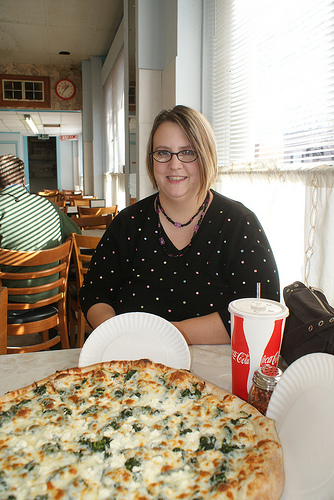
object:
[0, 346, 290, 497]
pizza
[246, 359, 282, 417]
jar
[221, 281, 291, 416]
cup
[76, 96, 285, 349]
woman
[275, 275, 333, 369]
purse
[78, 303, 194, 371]
plate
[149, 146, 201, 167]
glasses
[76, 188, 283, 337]
shirt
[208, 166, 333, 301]
curtain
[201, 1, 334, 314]
window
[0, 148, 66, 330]
man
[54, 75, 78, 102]
clock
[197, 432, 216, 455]
olives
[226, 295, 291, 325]
lid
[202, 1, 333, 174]
blinds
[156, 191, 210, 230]
necklace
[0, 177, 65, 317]
t-shirt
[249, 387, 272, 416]
red pepper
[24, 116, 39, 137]
light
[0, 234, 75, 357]
chair